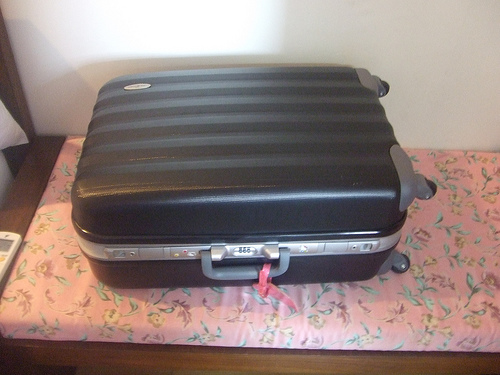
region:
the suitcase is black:
[47, 53, 446, 290]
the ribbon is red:
[241, 248, 326, 337]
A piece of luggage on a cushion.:
[61, 53, 468, 305]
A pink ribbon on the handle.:
[246, 264, 299, 316]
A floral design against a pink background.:
[416, 260, 489, 325]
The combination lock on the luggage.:
[233, 246, 259, 258]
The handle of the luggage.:
[191, 251, 296, 287]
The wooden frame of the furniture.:
[8, 329, 498, 369]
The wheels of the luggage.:
[393, 143, 446, 278]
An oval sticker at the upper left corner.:
[121, 76, 156, 95]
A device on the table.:
[0, 224, 25, 283]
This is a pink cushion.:
[7, 130, 498, 362]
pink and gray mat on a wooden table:
[1, 135, 496, 355]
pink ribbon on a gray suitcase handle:
[255, 265, 304, 313]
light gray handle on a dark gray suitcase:
[198, 253, 290, 282]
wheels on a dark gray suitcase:
[374, 73, 434, 276]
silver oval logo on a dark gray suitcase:
[121, 82, 153, 96]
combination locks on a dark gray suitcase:
[236, 244, 253, 258]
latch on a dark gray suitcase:
[101, 242, 146, 268]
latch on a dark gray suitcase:
[341, 240, 383, 258]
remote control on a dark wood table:
[0, 224, 22, 291]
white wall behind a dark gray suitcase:
[4, 1, 498, 147]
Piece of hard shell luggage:
[71, 63, 438, 291]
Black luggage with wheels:
[69, 63, 439, 291]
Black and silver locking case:
[69, 65, 441, 291]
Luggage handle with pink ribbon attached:
[198, 246, 298, 317]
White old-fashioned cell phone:
[0, 230, 22, 283]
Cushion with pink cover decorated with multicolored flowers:
[4, 131, 499, 352]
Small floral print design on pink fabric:
[5, 134, 498, 354]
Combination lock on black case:
[233, 244, 258, 256]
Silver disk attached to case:
[121, 81, 150, 91]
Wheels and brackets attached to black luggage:
[351, 64, 440, 275]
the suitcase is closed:
[44, 61, 440, 303]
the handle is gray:
[179, 233, 309, 315]